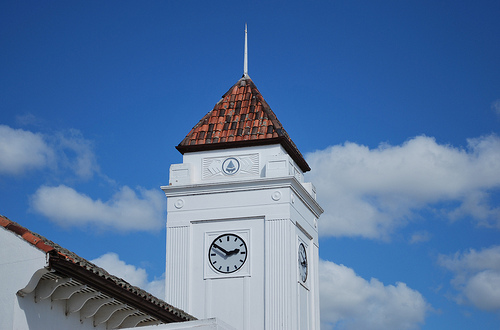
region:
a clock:
[182, 191, 255, 309]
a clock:
[211, 196, 266, 317]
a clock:
[162, 144, 264, 302]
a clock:
[185, 96, 297, 316]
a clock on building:
[192, 224, 284, 296]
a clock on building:
[182, 170, 257, 281]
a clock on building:
[190, 231, 311, 326]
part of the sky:
[339, 32, 399, 102]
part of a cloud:
[363, 155, 396, 178]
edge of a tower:
[286, 252, 298, 274]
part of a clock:
[291, 247, 308, 267]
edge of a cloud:
[374, 212, 426, 251]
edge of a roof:
[137, 292, 167, 316]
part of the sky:
[403, 257, 427, 291]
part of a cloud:
[364, 144, 414, 194]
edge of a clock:
[239, 240, 249, 262]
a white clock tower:
[136, 9, 321, 329]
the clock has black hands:
[208, 227, 249, 272]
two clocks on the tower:
[203, 225, 315, 285]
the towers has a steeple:
[224, 12, 259, 79]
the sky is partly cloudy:
[302, 65, 496, 327]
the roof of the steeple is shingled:
[162, 76, 292, 141]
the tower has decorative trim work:
[156, 182, 283, 212]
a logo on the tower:
[192, 154, 260, 179]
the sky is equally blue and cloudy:
[4, 120, 498, 329]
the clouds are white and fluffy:
[327, 135, 494, 326]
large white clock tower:
[158, 58, 350, 327]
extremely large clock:
[193, 221, 256, 286]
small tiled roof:
[164, 71, 327, 179]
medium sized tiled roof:
[1, 199, 226, 328]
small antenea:
[229, 11, 266, 81]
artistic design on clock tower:
[199, 150, 265, 187]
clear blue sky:
[10, 3, 465, 120]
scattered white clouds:
[308, 137, 496, 328]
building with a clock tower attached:
[0, 208, 225, 328]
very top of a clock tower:
[237, 15, 259, 77]